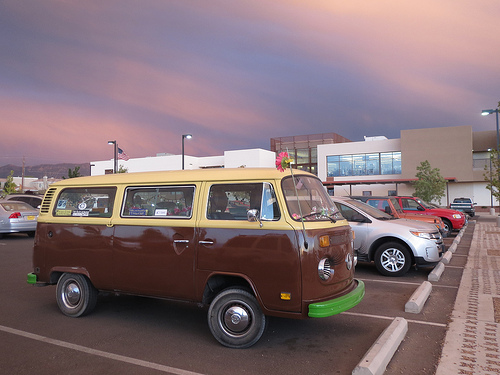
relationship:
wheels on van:
[56, 272, 268, 348] [27, 147, 366, 348]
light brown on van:
[35, 167, 351, 230] [27, 147, 366, 348]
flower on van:
[275, 149, 295, 173] [27, 147, 366, 348]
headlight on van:
[319, 257, 333, 281] [27, 147, 366, 348]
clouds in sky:
[1, 0, 499, 167] [1, 0, 500, 166]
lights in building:
[276, 148, 402, 178] [89, 124, 500, 212]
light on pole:
[185, 135, 193, 141] [181, 133, 186, 170]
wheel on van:
[208, 286, 268, 350] [27, 147, 366, 348]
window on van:
[120, 184, 196, 220] [27, 147, 366, 348]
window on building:
[326, 151, 403, 178] [89, 124, 500, 212]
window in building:
[326, 151, 403, 178] [89, 124, 500, 212]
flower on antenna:
[275, 149, 295, 173] [285, 147, 310, 250]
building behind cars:
[89, 124, 500, 212] [1, 145, 478, 349]